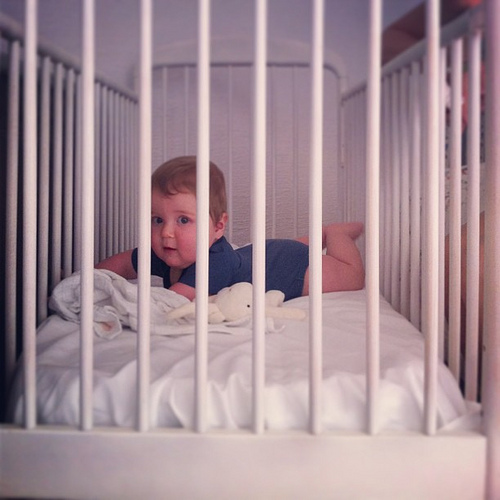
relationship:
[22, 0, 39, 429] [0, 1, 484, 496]
rail on baby bed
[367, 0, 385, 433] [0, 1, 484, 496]
rail on baby bed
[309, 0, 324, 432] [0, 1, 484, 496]
rail on baby bed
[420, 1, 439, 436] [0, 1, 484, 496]
rail on baby bed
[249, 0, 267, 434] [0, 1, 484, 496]
rail supporting baby bed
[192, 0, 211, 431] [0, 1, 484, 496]
rail supporting baby bed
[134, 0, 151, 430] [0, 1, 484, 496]
rail supporting baby bed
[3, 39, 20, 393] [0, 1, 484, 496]
rail supporting baby bed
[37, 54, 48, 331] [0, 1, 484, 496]
rail supporting baby bed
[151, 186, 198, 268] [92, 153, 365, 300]
face belonging to baby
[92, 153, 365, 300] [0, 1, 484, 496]
baby lying inside baby bed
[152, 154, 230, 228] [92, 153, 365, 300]
hair belonging to baby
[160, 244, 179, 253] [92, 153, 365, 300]
mouth belonging to baby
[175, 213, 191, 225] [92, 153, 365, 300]
eye belonging to baby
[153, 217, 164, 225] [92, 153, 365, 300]
eye belonging to baby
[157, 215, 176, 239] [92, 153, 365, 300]
nose belonging to baby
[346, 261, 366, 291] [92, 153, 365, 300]
knee belonging to baby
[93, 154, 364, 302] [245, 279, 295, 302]
baby lying on tummy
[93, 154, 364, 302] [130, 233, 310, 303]
baby wearing romper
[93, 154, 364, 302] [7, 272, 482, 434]
baby lying on top of crib sheet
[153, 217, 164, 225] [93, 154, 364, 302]
eye belonging to baby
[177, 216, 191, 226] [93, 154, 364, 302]
eye belonging to baby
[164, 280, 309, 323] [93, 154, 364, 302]
rabbit toy lying next to baby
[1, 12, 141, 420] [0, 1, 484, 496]
side holding up baby bed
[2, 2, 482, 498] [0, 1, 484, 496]
side holding up baby bed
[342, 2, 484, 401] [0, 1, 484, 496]
side holding up baby bed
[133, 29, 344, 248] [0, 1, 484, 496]
side holding up baby bed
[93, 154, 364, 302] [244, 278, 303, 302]
baby lying on stomach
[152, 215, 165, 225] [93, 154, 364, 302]
eye belonging to baby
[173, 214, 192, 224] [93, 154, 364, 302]
eye belonging to baby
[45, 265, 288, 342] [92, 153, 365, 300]
blanket lying in front of baby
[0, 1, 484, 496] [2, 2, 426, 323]
baby bed standing in front of wall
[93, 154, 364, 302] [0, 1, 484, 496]
baby in baby bed